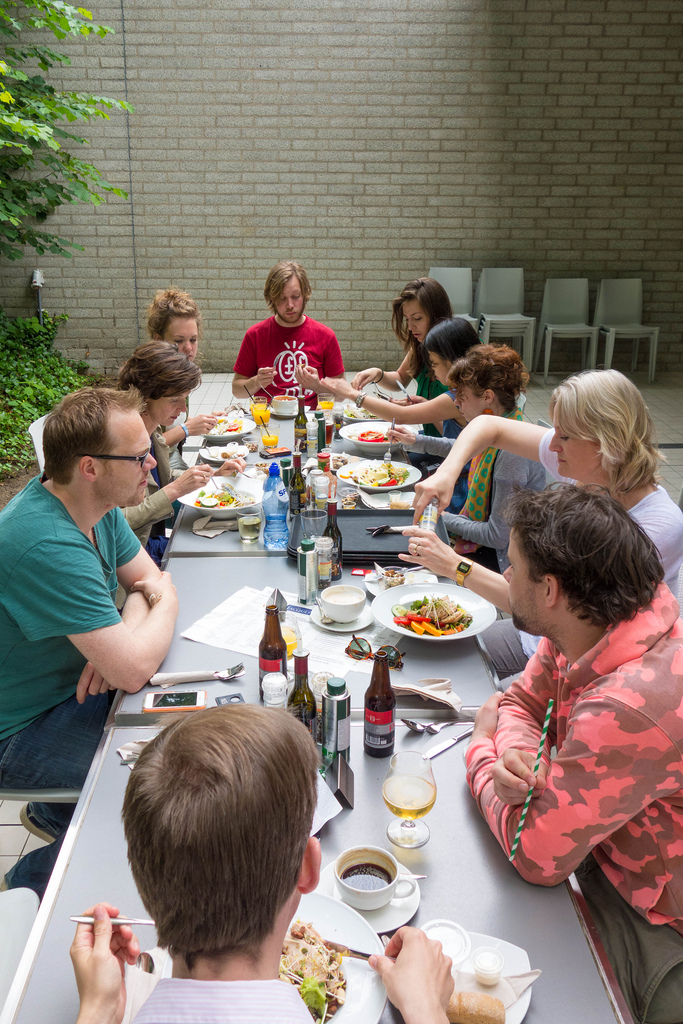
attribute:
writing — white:
[272, 343, 317, 397]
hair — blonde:
[548, 367, 662, 488]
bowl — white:
[369, 581, 496, 645]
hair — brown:
[395, 280, 447, 343]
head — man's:
[492, 493, 659, 649]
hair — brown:
[514, 489, 663, 616]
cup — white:
[334, 848, 414, 915]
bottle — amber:
[360, 651, 396, 756]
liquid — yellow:
[381, 773, 431, 813]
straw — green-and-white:
[507, 690, 555, 866]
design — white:
[270, 341, 315, 399]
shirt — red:
[234, 319, 344, 403]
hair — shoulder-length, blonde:
[555, 370, 664, 491]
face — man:
[48, 410, 163, 508]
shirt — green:
[0, 493, 120, 722]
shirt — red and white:
[241, 317, 335, 400]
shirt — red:
[230, 313, 349, 409]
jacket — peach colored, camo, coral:
[462, 582, 681, 938]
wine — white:
[381, 773, 438, 821]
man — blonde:
[67, 701, 456, 1022]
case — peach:
[146, 692, 201, 715]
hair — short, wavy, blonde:
[539, 360, 676, 495]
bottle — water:
[252, 460, 295, 556]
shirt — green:
[3, 473, 152, 741]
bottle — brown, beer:
[353, 644, 397, 763]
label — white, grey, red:
[363, 702, 396, 754]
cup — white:
[327, 845, 415, 919]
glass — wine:
[374, 751, 442, 859]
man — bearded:
[222, 259, 352, 422]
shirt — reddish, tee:
[225, 307, 351, 408]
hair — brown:
[501, 475, 668, 631]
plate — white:
[364, 568, 500, 654]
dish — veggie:
[383, 603, 453, 646]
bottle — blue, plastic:
[258, 454, 295, 557]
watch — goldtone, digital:
[448, 551, 477, 584]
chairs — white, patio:
[424, 252, 482, 368]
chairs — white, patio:
[474, 260, 538, 390]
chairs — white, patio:
[532, 266, 612, 386]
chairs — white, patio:
[584, 260, 668, 385]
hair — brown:
[124, 696, 326, 971]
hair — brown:
[114, 700, 318, 978]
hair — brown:
[118, 692, 329, 985]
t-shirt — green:
[1, 465, 146, 740]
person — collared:
[67, 701, 458, 1021]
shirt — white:
[126, 972, 328, 1020]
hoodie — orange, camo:
[468, 583, 680, 934]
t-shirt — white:
[538, 427, 682, 605]